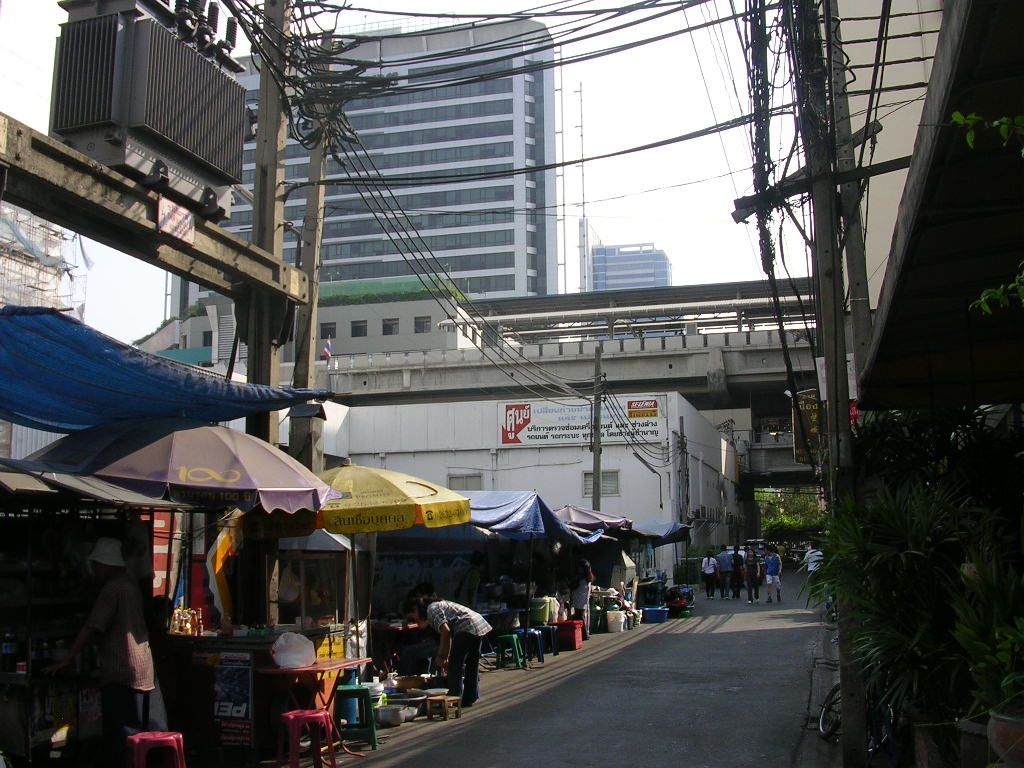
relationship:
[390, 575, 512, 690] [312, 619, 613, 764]
woman leaning next to street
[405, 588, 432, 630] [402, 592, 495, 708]
head of person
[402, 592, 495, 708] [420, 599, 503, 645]
person wearing shirt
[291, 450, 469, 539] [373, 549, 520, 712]
umbrella over woman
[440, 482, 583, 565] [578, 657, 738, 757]
tent next to street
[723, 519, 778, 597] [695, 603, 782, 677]
people on street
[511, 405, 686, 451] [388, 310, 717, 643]
sign on building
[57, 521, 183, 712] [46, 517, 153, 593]
man wearing hat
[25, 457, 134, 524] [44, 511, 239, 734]
awning above man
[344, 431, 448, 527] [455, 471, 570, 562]
canopy behind umbrella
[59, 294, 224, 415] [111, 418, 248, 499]
tarp above umbrella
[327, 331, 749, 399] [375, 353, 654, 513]
bridge above building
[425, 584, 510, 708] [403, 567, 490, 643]
person in shirt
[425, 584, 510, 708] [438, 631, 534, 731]
person in pants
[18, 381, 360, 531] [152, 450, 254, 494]
patio umbrella with pattern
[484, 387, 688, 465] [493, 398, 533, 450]
banner with symbols